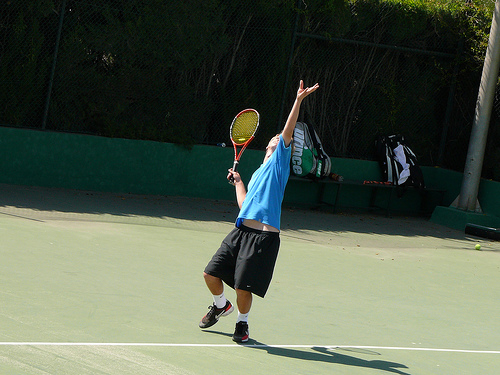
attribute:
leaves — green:
[373, 8, 482, 48]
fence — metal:
[81, 19, 378, 125]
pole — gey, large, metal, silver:
[455, 25, 499, 205]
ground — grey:
[5, 203, 451, 254]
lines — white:
[59, 325, 457, 367]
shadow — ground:
[249, 332, 359, 374]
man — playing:
[232, 101, 295, 336]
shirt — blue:
[238, 153, 291, 237]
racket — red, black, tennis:
[211, 93, 266, 173]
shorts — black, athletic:
[212, 215, 309, 297]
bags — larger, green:
[291, 111, 443, 191]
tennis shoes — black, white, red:
[201, 298, 258, 337]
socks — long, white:
[201, 290, 246, 318]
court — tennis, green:
[50, 229, 482, 374]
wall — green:
[59, 133, 217, 185]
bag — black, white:
[375, 123, 420, 192]